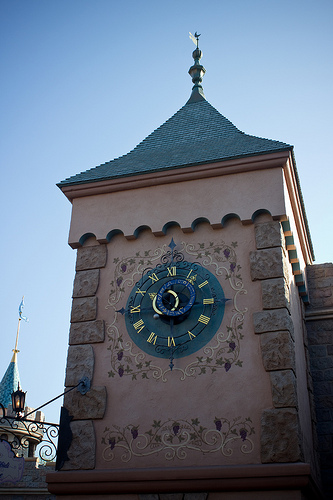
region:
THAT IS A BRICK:
[70, 248, 108, 265]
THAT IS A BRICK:
[69, 272, 98, 289]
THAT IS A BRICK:
[67, 300, 97, 318]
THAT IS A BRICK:
[66, 322, 101, 340]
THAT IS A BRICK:
[63, 349, 90, 380]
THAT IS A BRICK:
[59, 389, 106, 417]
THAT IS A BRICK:
[59, 421, 91, 479]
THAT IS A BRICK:
[260, 229, 279, 249]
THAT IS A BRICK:
[252, 254, 283, 274]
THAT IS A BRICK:
[248, 314, 287, 332]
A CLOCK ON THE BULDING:
[132, 246, 218, 350]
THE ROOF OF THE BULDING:
[187, 121, 199, 135]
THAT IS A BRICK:
[64, 419, 98, 461]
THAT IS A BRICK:
[262, 407, 299, 455]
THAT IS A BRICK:
[274, 376, 295, 404]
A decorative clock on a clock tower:
[116, 241, 231, 369]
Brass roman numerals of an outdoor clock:
[127, 258, 219, 348]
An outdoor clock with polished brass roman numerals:
[118, 247, 224, 360]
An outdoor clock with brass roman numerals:
[127, 256, 219, 354]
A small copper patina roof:
[48, 28, 300, 187]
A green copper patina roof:
[56, 101, 296, 189]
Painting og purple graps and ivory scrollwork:
[98, 413, 264, 467]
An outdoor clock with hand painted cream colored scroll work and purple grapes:
[105, 238, 251, 382]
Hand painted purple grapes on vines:
[206, 409, 258, 444]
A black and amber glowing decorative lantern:
[7, 379, 28, 414]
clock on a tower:
[113, 250, 243, 368]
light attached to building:
[7, 380, 31, 419]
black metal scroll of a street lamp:
[7, 414, 61, 467]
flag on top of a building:
[8, 291, 34, 322]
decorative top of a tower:
[183, 26, 210, 86]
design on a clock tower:
[100, 414, 265, 462]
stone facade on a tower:
[263, 327, 305, 460]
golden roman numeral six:
[161, 329, 182, 355]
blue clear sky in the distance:
[17, 68, 112, 137]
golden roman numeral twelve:
[163, 261, 179, 278]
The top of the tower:
[182, 27, 208, 106]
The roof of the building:
[161, 120, 236, 157]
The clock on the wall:
[110, 234, 241, 371]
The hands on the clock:
[162, 291, 231, 369]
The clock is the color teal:
[131, 264, 226, 354]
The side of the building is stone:
[247, 224, 305, 460]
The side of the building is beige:
[84, 182, 272, 234]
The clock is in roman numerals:
[131, 313, 213, 347]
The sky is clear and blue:
[4, 5, 178, 106]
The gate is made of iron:
[2, 409, 59, 460]